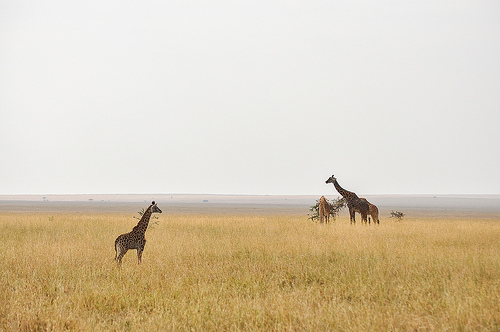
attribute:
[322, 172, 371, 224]
giraffe — tan, tall, large, little, open, standing, wild, standing up, lookig, looking, taller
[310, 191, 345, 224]
tree — shorter, isolated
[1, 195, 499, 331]
grassland — light, flat, dry, brownish, tall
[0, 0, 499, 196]
sky — gray, light, clear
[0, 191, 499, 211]
horizon — flat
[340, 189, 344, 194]
spot — brown